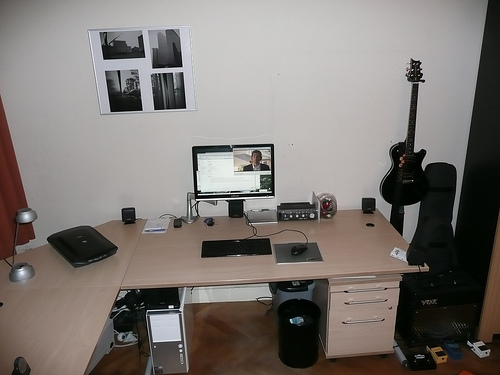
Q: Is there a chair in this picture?
A: No, there are no chairs.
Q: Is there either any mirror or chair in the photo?
A: No, there are no chairs or mirrors.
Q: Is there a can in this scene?
A: Yes, there is a can.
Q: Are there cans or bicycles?
A: Yes, there is a can.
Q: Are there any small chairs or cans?
A: Yes, there is a small can.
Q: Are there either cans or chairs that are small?
A: Yes, the can is small.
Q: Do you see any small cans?
A: Yes, there is a small can.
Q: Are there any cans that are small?
A: Yes, there is a can that is small.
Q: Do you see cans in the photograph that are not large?
A: Yes, there is a small can.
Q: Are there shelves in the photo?
A: No, there are no shelves.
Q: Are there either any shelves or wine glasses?
A: No, there are no shelves or wine glasses.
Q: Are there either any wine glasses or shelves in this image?
A: No, there are no shelves or wine glasses.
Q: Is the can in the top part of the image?
A: No, the can is in the bottom of the image.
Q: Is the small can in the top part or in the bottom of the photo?
A: The can is in the bottom of the image.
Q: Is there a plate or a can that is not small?
A: No, there is a can but it is small.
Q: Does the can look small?
A: Yes, the can is small.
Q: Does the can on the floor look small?
A: Yes, the can is small.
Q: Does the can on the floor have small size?
A: Yes, the can is small.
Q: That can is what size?
A: The can is small.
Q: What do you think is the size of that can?
A: The can is small.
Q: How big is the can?
A: The can is small.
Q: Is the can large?
A: No, the can is small.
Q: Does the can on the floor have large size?
A: No, the can is small.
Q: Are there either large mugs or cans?
A: No, there is a can but it is small.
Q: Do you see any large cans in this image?
A: No, there is a can but it is small.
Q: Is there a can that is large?
A: No, there is a can but it is small.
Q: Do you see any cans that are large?
A: No, there is a can but it is small.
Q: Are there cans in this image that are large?
A: No, there is a can but it is small.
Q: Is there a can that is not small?
A: No, there is a can but it is small.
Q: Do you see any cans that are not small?
A: No, there is a can but it is small.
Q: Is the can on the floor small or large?
A: The can is small.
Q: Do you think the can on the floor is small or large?
A: The can is small.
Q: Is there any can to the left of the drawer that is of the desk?
A: Yes, there is a can to the left of the drawer.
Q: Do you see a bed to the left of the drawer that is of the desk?
A: No, there is a can to the left of the drawer.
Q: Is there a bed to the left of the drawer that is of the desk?
A: No, there is a can to the left of the drawer.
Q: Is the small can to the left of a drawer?
A: Yes, the can is to the left of a drawer.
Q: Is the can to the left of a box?
A: No, the can is to the left of a drawer.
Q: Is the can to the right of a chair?
A: No, the can is to the right of the computer.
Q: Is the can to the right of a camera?
A: No, the can is to the right of the computer.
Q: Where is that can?
A: The can is on the floor.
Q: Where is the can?
A: The can is on the floor.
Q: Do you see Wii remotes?
A: No, there are no Wii remotes.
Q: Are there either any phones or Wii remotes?
A: No, there are no Wii remotes or phones.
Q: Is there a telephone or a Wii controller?
A: No, there are no Wii controllers or phones.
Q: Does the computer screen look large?
A: Yes, the screen is large.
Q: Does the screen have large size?
A: Yes, the screen is large.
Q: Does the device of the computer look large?
A: Yes, the screen is large.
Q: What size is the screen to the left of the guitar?
A: The screen is large.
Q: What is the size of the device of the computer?
A: The screen is large.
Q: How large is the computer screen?
A: The screen is large.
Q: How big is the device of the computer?
A: The screen is large.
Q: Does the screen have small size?
A: No, the screen is large.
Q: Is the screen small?
A: No, the screen is large.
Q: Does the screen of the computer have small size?
A: No, the screen is large.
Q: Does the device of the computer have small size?
A: No, the screen is large.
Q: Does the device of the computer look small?
A: No, the screen is large.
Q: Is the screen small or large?
A: The screen is large.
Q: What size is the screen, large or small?
A: The screen is large.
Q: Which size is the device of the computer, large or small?
A: The screen is large.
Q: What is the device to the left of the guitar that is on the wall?
A: The device is a screen.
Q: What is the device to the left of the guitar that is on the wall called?
A: The device is a screen.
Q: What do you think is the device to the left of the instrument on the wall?
A: The device is a screen.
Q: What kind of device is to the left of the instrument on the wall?
A: The device is a screen.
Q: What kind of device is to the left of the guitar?
A: The device is a screen.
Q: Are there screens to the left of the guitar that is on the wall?
A: Yes, there is a screen to the left of the guitar.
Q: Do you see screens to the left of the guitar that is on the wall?
A: Yes, there is a screen to the left of the guitar.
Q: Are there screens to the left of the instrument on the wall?
A: Yes, there is a screen to the left of the guitar.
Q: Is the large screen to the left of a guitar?
A: Yes, the screen is to the left of a guitar.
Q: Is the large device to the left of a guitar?
A: Yes, the screen is to the left of a guitar.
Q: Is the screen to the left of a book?
A: No, the screen is to the left of a guitar.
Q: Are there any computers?
A: Yes, there is a computer.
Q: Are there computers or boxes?
A: Yes, there is a computer.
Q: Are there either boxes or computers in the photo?
A: Yes, there is a computer.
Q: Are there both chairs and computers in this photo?
A: No, there is a computer but no chairs.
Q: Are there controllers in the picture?
A: No, there are no controllers.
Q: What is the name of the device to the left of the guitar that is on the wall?
A: The device is a computer.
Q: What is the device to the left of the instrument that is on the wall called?
A: The device is a computer.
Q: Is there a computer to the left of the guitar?
A: Yes, there is a computer to the left of the guitar.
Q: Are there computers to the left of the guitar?
A: Yes, there is a computer to the left of the guitar.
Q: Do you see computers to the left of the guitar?
A: Yes, there is a computer to the left of the guitar.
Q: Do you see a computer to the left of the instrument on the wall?
A: Yes, there is a computer to the left of the guitar.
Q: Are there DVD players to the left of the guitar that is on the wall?
A: No, there is a computer to the left of the guitar.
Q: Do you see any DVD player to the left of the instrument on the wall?
A: No, there is a computer to the left of the guitar.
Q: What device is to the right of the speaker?
A: The device is a computer.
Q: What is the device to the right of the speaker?
A: The device is a computer.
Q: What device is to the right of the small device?
A: The device is a computer.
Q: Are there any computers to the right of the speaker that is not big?
A: Yes, there is a computer to the right of the speaker.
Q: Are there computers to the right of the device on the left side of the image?
A: Yes, there is a computer to the right of the speaker.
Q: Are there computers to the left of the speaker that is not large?
A: No, the computer is to the right of the speaker.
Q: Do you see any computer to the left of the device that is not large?
A: No, the computer is to the right of the speaker.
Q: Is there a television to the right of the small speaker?
A: No, there is a computer to the right of the speaker.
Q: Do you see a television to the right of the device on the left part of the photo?
A: No, there is a computer to the right of the speaker.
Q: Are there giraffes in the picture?
A: No, there are no giraffes.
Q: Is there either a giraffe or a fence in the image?
A: No, there are no giraffes or fences.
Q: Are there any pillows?
A: No, there are no pillows.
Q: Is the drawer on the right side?
A: Yes, the drawer is on the right of the image.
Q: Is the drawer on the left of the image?
A: No, the drawer is on the right of the image.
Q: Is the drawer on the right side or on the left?
A: The drawer is on the right of the image.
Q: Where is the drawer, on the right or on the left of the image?
A: The drawer is on the right of the image.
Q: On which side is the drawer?
A: The drawer is on the right of the image.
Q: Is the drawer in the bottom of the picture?
A: Yes, the drawer is in the bottom of the image.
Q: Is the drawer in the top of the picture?
A: No, the drawer is in the bottom of the image.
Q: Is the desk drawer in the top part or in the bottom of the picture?
A: The drawer is in the bottom of the image.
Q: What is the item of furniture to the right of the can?
A: The piece of furniture is a drawer.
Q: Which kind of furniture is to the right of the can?
A: The piece of furniture is a drawer.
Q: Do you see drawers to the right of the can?
A: Yes, there is a drawer to the right of the can.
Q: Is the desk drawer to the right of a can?
A: Yes, the drawer is to the right of a can.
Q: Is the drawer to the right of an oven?
A: No, the drawer is to the right of a can.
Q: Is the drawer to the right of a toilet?
A: No, the drawer is to the right of the computer.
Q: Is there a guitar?
A: Yes, there is a guitar.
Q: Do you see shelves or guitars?
A: Yes, there is a guitar.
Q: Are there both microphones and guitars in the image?
A: No, there is a guitar but no microphones.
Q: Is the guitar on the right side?
A: Yes, the guitar is on the right of the image.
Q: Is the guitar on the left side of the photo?
A: No, the guitar is on the right of the image.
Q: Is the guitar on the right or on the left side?
A: The guitar is on the right of the image.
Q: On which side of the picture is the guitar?
A: The guitar is on the right of the image.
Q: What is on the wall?
A: The guitar is on the wall.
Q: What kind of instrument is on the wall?
A: The instrument is a guitar.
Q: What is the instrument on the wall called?
A: The instrument is a guitar.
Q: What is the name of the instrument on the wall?
A: The instrument is a guitar.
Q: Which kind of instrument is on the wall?
A: The instrument is a guitar.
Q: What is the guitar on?
A: The guitar is on the wall.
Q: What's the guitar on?
A: The guitar is on the wall.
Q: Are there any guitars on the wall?
A: Yes, there is a guitar on the wall.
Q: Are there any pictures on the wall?
A: No, there is a guitar on the wall.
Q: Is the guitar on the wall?
A: Yes, the guitar is on the wall.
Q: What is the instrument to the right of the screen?
A: The instrument is a guitar.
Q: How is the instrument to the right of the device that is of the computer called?
A: The instrument is a guitar.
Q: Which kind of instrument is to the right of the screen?
A: The instrument is a guitar.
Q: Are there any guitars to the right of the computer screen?
A: Yes, there is a guitar to the right of the screen.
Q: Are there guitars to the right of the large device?
A: Yes, there is a guitar to the right of the screen.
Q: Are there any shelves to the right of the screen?
A: No, there is a guitar to the right of the screen.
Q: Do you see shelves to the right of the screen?
A: No, there is a guitar to the right of the screen.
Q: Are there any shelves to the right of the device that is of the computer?
A: No, there is a guitar to the right of the screen.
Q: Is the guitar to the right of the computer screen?
A: Yes, the guitar is to the right of the screen.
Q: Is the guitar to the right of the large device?
A: Yes, the guitar is to the right of the screen.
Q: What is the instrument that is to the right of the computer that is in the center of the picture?
A: The instrument is a guitar.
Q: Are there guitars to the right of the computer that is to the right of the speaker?
A: Yes, there is a guitar to the right of the computer.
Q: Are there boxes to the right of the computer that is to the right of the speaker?
A: No, there is a guitar to the right of the computer.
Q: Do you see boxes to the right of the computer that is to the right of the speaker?
A: No, there is a guitar to the right of the computer.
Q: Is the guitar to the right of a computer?
A: Yes, the guitar is to the right of a computer.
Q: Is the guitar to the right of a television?
A: No, the guitar is to the right of a computer.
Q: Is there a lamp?
A: Yes, there is a lamp.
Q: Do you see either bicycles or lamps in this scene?
A: Yes, there is a lamp.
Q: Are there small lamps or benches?
A: Yes, there is a small lamp.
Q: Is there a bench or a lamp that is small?
A: Yes, the lamp is small.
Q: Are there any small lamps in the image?
A: Yes, there is a small lamp.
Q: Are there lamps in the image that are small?
A: Yes, there is a lamp that is small.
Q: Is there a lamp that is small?
A: Yes, there is a lamp that is small.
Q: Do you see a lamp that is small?
A: Yes, there is a lamp that is small.